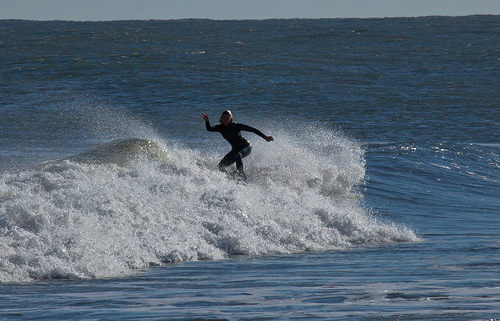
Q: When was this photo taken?
A: During the daytime.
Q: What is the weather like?
A: Sunny.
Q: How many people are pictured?
A: One.